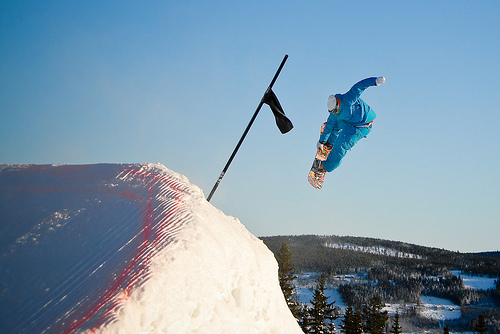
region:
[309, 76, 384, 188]
man is in the air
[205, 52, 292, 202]
flag is black and leaning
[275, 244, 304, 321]
tree is green and tall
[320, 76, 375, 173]
man has on blue outfit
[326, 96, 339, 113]
man has on a white snow cap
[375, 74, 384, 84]
man has on white gloves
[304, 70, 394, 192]
a man in blue falling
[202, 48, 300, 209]
a pole sticking in the air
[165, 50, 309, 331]
a black pole stuck in the snow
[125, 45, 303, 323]
ski caught in a hill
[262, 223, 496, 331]
a snowy field with trees on it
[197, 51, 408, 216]
a man falls off his skiis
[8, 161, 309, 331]
a large snowy mountain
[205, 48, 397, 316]
a man falls off of a cliff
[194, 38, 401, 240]
skier does a trick int he air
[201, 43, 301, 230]
a ski pole in the snow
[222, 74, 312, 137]
A flag flying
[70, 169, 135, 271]
A ramp in the photo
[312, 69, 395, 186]
A person skating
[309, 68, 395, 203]
A person in the air skating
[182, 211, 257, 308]
Snow on the ramp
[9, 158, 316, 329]
The mound of snow.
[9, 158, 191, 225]
The snow has red lines in it.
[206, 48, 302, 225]
The black post in the snow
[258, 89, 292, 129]
The post has a flag on it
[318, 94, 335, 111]
The helmet the man is wearing.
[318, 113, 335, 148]
The left hand of the man.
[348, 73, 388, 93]
The right hand of the man.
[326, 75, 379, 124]
The blue jacket the man is wearing.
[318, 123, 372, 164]
The man is wearing a blue pant.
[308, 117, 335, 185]
The snowboard is colorful.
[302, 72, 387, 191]
Snowboarder flying through the air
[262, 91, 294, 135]
Black flag on a pole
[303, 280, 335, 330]
PIne tree below a hill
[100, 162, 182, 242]
Red marks in the snow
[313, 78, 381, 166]
the snow suit is blue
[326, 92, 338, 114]
the winter hat is white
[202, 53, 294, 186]
the black flag is on the pole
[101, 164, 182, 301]
the paint on the snow is red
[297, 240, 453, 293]
trees are on the mountain side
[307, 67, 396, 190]
a snowboarder doing a trick in the air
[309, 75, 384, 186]
the snowboarder is mid air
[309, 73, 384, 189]
the snowboarder is in motion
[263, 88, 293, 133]
the flag is black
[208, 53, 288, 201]
the pole is black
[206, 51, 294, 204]
the flag on the pole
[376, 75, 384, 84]
the glove is white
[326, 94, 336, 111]
the hat is white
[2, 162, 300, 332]
the spray paint on the snow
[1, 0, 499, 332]
the blue sky above the snow